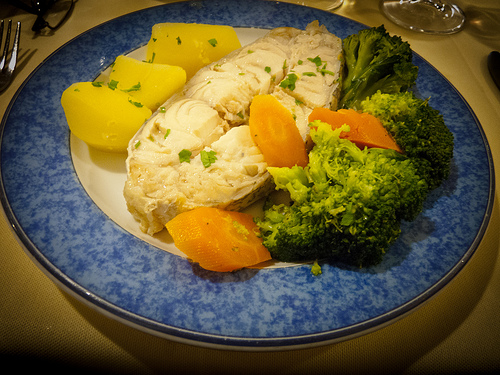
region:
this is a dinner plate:
[9, 3, 499, 356]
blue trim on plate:
[20, 7, 496, 372]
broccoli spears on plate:
[274, 5, 463, 286]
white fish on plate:
[77, 20, 369, 233]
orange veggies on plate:
[160, 191, 283, 276]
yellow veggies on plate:
[60, 6, 262, 165]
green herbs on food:
[70, 34, 357, 199]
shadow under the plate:
[95, 322, 142, 344]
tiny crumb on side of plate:
[308, 252, 327, 278]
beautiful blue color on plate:
[128, 273, 278, 327]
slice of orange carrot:
[247, 100, 307, 165]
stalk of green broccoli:
[281, 169, 413, 241]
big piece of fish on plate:
[135, 111, 249, 176]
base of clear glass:
[390, 9, 465, 41]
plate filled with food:
[90, 13, 462, 285]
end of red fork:
[5, 13, 36, 43]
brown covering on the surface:
[27, 304, 97, 344]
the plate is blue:
[277, 290, 329, 321]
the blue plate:
[125, 261, 171, 291]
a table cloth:
[438, 43, 473, 70]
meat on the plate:
[198, 78, 244, 108]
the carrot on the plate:
[258, 108, 298, 152]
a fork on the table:
[7, 25, 26, 65]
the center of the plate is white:
[96, 165, 113, 193]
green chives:
[176, 148, 216, 166]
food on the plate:
[156, 38, 413, 250]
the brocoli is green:
[312, 195, 388, 240]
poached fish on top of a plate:
[126, 19, 348, 235]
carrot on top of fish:
[247, 92, 305, 171]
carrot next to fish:
[166, 207, 272, 273]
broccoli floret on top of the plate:
[337, 24, 416, 107]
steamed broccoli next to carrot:
[259, 122, 428, 269]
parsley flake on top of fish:
[200, 149, 217, 169]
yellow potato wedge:
[145, 21, 242, 76]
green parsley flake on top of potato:
[207, 37, 217, 47]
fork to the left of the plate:
[0, 18, 22, 95]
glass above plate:
[381, 2, 464, 37]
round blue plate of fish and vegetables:
[5, 0, 497, 327]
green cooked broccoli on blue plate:
[256, 23, 458, 263]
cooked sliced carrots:
[155, 95, 400, 269]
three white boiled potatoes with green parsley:
[53, 16, 253, 164]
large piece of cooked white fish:
[118, 19, 350, 229]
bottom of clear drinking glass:
[370, 0, 477, 39]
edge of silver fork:
[0, 15, 39, 92]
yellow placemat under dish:
[6, 0, 498, 353]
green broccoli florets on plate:
[253, 22, 434, 264]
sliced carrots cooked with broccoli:
[171, 93, 396, 268]